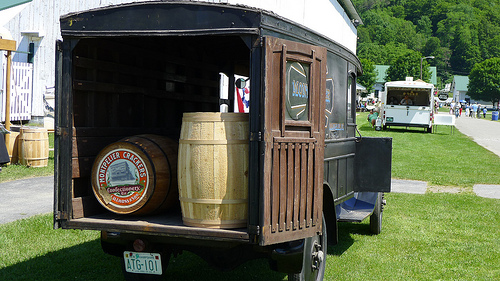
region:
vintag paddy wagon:
[50, 1, 399, 280]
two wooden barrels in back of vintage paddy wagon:
[86, 91, 256, 232]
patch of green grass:
[412, 208, 477, 275]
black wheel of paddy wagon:
[288, 208, 340, 278]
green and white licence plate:
[116, 245, 194, 278]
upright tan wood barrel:
[11, 116, 51, 170]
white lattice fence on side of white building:
[1, 53, 33, 123]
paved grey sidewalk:
[457, 116, 498, 153]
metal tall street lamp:
[416, 53, 438, 80]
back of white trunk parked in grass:
[372, 71, 443, 141]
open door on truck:
[42, 19, 283, 243]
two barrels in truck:
[87, 96, 259, 233]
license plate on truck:
[114, 244, 168, 276]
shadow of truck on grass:
[26, 238, 106, 273]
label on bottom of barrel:
[92, 148, 153, 209]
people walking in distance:
[439, 96, 484, 126]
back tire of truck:
[288, 204, 337, 277]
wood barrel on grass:
[13, 119, 50, 176]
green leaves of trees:
[398, 9, 475, 59]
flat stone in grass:
[394, 173, 442, 198]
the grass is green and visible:
[304, 91, 434, 238]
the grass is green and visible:
[360, 123, 436, 278]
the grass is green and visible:
[400, 172, 442, 268]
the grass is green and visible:
[375, 160, 425, 272]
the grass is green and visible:
[383, 147, 428, 209]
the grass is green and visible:
[411, 112, 472, 274]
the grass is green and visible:
[336, 91, 399, 247]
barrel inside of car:
[181, 110, 264, 262]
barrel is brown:
[158, 90, 266, 235]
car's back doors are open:
[72, 35, 321, 237]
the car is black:
[57, 2, 404, 244]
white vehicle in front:
[378, 64, 450, 154]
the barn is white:
[0, 0, 406, 137]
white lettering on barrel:
[89, 144, 153, 206]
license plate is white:
[123, 237, 168, 274]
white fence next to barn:
[6, 60, 38, 119]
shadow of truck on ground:
[3, 230, 107, 279]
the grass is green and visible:
[418, 178, 456, 271]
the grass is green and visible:
[447, 198, 487, 279]